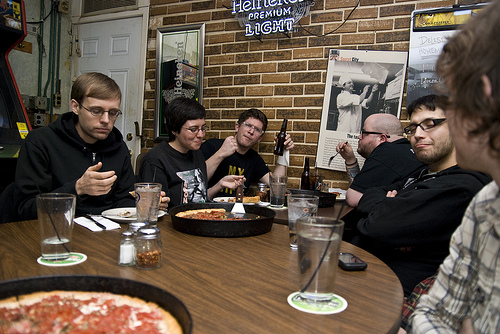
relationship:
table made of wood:
[1, 211, 405, 333] [225, 263, 253, 286]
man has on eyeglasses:
[12, 71, 171, 218] [79, 104, 124, 118]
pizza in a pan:
[0, 290, 181, 333] [0, 275, 194, 334]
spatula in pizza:
[230, 186, 248, 216] [0, 290, 181, 333]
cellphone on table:
[339, 252, 368, 270] [1, 211, 405, 333]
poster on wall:
[315, 47, 408, 172] [140, 1, 499, 198]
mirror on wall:
[155, 22, 205, 142] [140, 1, 499, 198]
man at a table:
[12, 71, 171, 218] [1, 211, 405, 333]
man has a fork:
[12, 71, 171, 218] [329, 142, 347, 162]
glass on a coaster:
[297, 215, 345, 303] [289, 289, 347, 316]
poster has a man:
[315, 47, 408, 172] [335, 77, 377, 138]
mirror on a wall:
[155, 22, 205, 142] [140, 1, 499, 198]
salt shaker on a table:
[116, 230, 134, 266] [1, 211, 405, 333]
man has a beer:
[12, 71, 171, 218] [276, 117, 289, 154]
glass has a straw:
[297, 215, 345, 303] [300, 201, 345, 296]